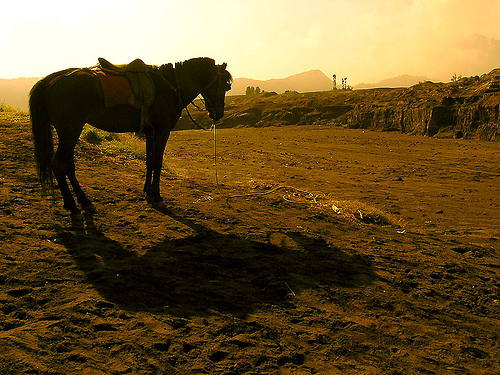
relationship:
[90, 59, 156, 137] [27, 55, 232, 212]
saddle sitting on horse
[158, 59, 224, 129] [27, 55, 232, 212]
harness on horse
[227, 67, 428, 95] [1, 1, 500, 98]
mountains are in far distance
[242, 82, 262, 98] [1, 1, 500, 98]
tree like growths in distance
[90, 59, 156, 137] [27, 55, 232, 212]
saddle on horse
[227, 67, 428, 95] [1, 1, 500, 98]
tallest peak in distance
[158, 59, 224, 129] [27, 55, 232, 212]
reins on horse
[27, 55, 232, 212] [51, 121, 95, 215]
horse has two back legs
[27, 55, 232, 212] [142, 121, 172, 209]
horse has two front legs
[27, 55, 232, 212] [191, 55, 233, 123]
horse has a head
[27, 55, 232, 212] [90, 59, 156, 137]
horse with saddle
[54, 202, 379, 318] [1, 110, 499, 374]
shadow of horse on dirt ground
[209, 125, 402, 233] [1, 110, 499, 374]
rope lying in dirt ground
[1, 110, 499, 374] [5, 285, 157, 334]
dirt ground with footprints